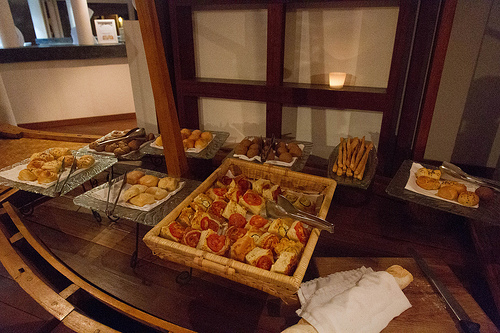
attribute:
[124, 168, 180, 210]
baguette — cut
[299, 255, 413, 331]
towel — white